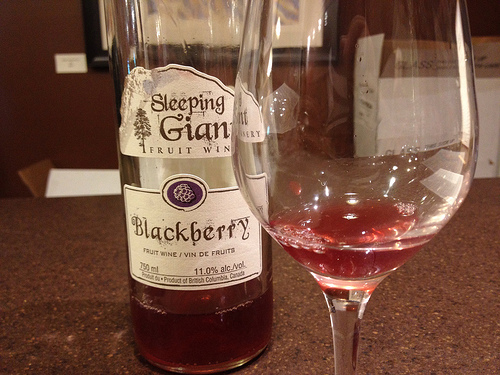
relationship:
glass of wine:
[242, 6, 483, 365] [263, 189, 434, 290]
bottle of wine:
[115, 1, 291, 371] [132, 269, 273, 366]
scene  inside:
[8, 4, 490, 369] [14, 8, 481, 221]